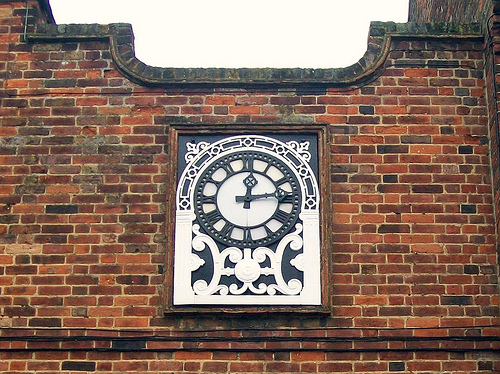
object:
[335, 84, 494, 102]
brick wall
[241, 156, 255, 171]
black twelve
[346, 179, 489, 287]
brick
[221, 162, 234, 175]
number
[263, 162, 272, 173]
number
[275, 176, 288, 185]
number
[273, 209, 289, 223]
number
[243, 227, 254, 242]
numeral six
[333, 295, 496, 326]
brick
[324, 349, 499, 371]
brick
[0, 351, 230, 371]
brick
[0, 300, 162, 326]
brick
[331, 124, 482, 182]
brick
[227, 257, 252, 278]
edge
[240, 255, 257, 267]
part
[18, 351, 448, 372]
wall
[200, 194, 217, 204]
nine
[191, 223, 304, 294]
scroll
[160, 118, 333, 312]
frame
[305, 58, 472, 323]
wall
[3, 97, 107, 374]
wall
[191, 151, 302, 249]
clock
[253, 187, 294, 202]
hand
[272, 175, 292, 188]
roman numerals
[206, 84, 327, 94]
bricks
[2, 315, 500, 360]
ledge